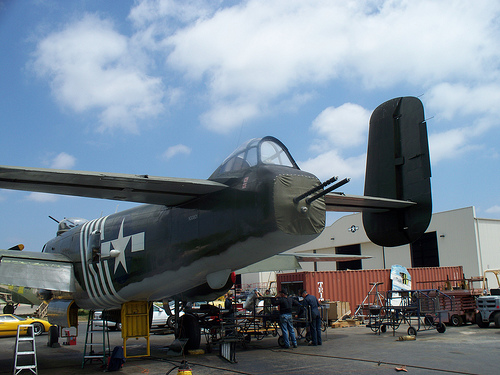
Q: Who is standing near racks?
A: Two men.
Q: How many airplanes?
A: One.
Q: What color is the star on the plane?
A: White.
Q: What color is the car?
A: Yellow.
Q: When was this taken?
A: During the day time.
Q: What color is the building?
A: Tan.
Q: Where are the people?
A: On tarmac.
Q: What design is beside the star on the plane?
A: Stripes.